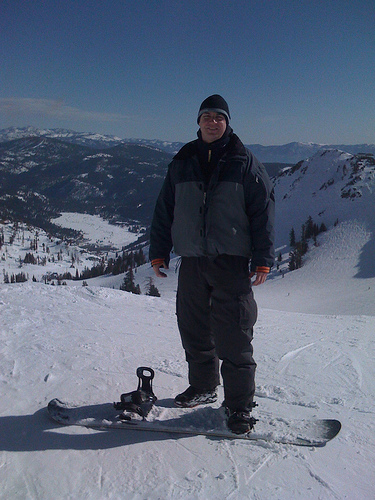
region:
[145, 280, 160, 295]
green tree in background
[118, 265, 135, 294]
green tree in background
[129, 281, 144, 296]
green tree in background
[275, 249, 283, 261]
green tree in background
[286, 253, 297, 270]
green tree in background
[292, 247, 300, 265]
green tree in background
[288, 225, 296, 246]
green tree in background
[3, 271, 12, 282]
green tree in background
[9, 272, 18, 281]
green tree in background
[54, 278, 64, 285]
green tree in background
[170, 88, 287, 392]
man on top of mountain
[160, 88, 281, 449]
man on a snow board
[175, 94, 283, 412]
man in black snow pants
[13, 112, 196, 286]
mountains behind a guy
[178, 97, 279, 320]
man with grey and black jacket and hat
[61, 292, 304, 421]
snow on a hill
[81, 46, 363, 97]
blue sky over the mountains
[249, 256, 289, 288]
orange cuff on the coat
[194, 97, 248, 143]
man wearing a hat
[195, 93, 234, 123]
man has black cap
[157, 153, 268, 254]
black and grey coat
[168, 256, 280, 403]
man has black pants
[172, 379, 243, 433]
man has black boots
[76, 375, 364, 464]
white and snow covered skis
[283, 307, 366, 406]
white snow on hill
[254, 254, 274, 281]
orange cuffs on coat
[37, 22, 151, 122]
white and blue sky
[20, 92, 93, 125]
white clouds low in sky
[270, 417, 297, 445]
snowboard is snow covered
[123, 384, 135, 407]
foot brace of snowboard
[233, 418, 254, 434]
man in black boots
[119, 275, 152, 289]
3 evergreen trees in back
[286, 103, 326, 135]
sky is a dim blue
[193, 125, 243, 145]
man is standing smiling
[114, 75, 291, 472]
skier on hill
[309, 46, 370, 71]
white clouds in blue sky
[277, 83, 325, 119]
white clouds in blue sky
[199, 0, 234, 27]
white clouds in blue sky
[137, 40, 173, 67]
white clouds in blue sky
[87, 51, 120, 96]
white clouds in blue sky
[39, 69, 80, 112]
white clouds in blue sky